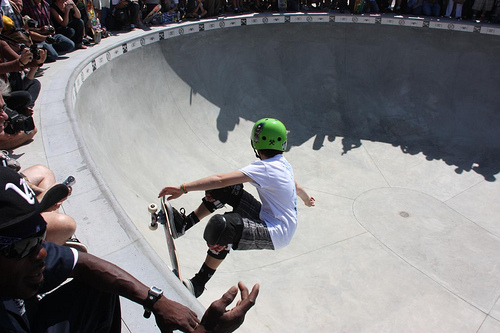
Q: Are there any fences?
A: No, there are no fences.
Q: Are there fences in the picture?
A: No, there are no fences.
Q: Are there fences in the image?
A: No, there are no fences.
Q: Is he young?
A: Yes, the boy is young.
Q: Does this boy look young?
A: Yes, the boy is young.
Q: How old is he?
A: The boy is young.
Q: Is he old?
A: No, the boy is young.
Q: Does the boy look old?
A: No, the boy is young.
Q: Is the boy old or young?
A: The boy is young.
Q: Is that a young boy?
A: Yes, that is a young boy.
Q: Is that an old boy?
A: No, that is a young boy.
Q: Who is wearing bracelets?
A: The boy is wearing bracelets.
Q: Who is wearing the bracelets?
A: The boy is wearing bracelets.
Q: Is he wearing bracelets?
A: Yes, the boy is wearing bracelets.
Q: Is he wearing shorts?
A: No, the boy is wearing bracelets.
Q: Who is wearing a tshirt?
A: The boy is wearing a tshirt.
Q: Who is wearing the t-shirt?
A: The boy is wearing a tshirt.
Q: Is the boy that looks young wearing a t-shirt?
A: Yes, the boy is wearing a t-shirt.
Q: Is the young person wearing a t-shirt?
A: Yes, the boy is wearing a t-shirt.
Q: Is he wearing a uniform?
A: No, the boy is wearing a t-shirt.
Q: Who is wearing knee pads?
A: The boy is wearing knee pads.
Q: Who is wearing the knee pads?
A: The boy is wearing knee pads.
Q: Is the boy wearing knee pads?
A: Yes, the boy is wearing knee pads.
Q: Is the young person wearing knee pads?
A: Yes, the boy is wearing knee pads.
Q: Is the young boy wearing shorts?
A: No, the boy is wearing knee pads.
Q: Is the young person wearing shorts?
A: No, the boy is wearing knee pads.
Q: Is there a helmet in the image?
A: Yes, there is a helmet.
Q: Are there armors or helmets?
A: Yes, there is a helmet.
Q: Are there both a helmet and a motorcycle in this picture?
A: No, there is a helmet but no motorcycles.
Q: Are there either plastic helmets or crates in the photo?
A: Yes, there is a plastic helmet.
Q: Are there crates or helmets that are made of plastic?
A: Yes, the helmet is made of plastic.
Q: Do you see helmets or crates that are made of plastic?
A: Yes, the helmet is made of plastic.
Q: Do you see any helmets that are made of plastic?
A: Yes, there is a helmet that is made of plastic.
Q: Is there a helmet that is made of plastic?
A: Yes, there is a helmet that is made of plastic.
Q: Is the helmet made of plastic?
A: Yes, the helmet is made of plastic.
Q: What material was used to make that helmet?
A: The helmet is made of plastic.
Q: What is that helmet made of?
A: The helmet is made of plastic.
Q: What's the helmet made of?
A: The helmet is made of plastic.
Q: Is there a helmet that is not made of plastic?
A: No, there is a helmet but it is made of plastic.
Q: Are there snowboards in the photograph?
A: No, there are no snowboards.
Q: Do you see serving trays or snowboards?
A: No, there are no snowboards or serving trays.